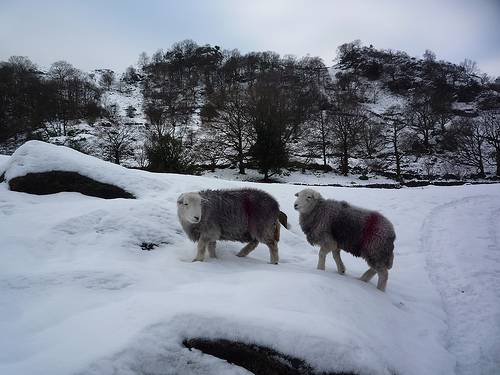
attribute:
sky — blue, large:
[2, 0, 499, 82]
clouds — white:
[26, 14, 83, 64]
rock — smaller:
[30, 197, 232, 244]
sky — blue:
[28, 8, 434, 44]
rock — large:
[1, 140, 161, 200]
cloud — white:
[210, 0, 479, 62]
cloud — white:
[474, 52, 499, 75]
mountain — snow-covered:
[99, 84, 257, 174]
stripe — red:
[354, 206, 381, 250]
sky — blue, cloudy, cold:
[2, 4, 492, 94]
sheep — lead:
[150, 162, 294, 280]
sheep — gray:
[288, 189, 390, 289]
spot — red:
[356, 210, 381, 256]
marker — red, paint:
[364, 212, 378, 247]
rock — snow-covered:
[10, 137, 136, 231]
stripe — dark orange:
[352, 211, 382, 258]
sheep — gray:
[177, 191, 279, 265]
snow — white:
[57, 245, 476, 347]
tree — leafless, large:
[375, 107, 419, 187]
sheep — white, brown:
[291, 187, 398, 295]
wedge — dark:
[191, 332, 313, 373]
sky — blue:
[47, 2, 467, 42]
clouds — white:
[1, 0, 499, 74]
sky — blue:
[2, 3, 499, 75]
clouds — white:
[2, 2, 498, 82]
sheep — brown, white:
[173, 185, 289, 266]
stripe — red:
[221, 192, 254, 236]